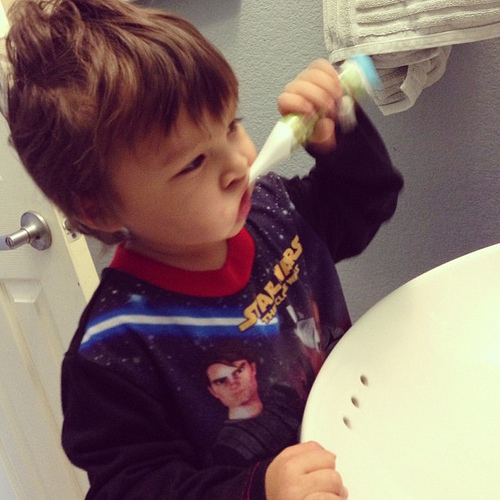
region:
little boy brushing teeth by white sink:
[6, 18, 486, 355]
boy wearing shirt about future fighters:
[55, 166, 355, 492]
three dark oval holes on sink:
[331, 365, 371, 430]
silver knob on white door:
[0, 6, 100, 422]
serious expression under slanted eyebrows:
[195, 335, 270, 430]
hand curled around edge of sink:
[261, 431, 356, 496]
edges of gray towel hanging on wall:
[316, 0, 496, 125]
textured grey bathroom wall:
[136, 0, 496, 320]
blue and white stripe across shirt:
[70, 301, 290, 346]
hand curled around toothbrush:
[248, 55, 383, 186]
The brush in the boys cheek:
[216, 191, 238, 236]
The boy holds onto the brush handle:
[263, 47, 373, 152]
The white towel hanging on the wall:
[317, 0, 498, 115]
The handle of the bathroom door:
[0, 206, 51, 263]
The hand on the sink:
[266, 433, 358, 499]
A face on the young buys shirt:
[194, 339, 275, 434]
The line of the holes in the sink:
[337, 364, 381, 441]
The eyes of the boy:
[145, 106, 251, 183]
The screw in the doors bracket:
[69, 230, 86, 243]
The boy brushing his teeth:
[1, 1, 406, 499]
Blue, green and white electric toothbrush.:
[239, 50, 379, 193]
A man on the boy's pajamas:
[193, 338, 304, 468]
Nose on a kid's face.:
[211, 141, 249, 186]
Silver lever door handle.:
[1, 228, 33, 249]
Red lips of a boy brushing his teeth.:
[233, 175, 251, 224]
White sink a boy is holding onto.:
[301, 242, 496, 499]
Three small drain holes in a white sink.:
[343, 372, 369, 429]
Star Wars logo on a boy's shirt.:
[232, 235, 304, 331]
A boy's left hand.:
[273, 59, 346, 147]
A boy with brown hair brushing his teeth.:
[3, 0, 401, 499]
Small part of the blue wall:
[432, 153, 464, 183]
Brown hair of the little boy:
[68, 39, 136, 96]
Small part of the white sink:
[391, 315, 421, 341]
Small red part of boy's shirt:
[166, 271, 191, 288]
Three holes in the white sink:
[342, 372, 372, 442]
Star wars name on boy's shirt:
[241, 232, 297, 337]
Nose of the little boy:
[221, 155, 247, 181]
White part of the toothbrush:
[263, 130, 285, 152]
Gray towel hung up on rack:
[350, 8, 425, 38]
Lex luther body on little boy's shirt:
[188, 345, 289, 453]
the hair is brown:
[38, 18, 195, 134]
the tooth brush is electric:
[256, 85, 369, 177]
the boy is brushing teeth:
[36, 67, 408, 487]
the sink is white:
[328, 279, 496, 499]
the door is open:
[3, 68, 125, 498]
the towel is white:
[332, 12, 455, 91]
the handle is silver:
[1, 223, 39, 272]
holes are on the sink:
[338, 371, 378, 435]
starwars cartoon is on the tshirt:
[158, 280, 335, 486]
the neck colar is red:
[156, 260, 258, 289]